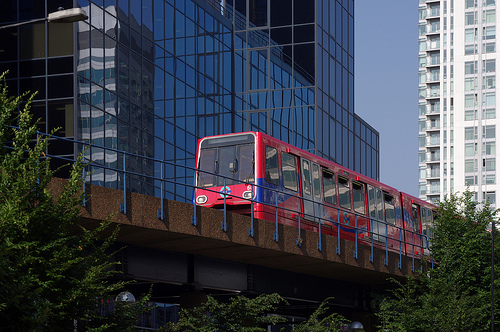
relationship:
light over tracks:
[45, 5, 89, 27] [1, 166, 500, 290]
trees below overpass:
[375, 189, 499, 332] [1, 118, 499, 315]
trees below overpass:
[163, 287, 350, 332] [1, 118, 499, 315]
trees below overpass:
[1, 65, 165, 331] [1, 118, 499, 315]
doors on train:
[296, 153, 328, 228] [186, 128, 500, 273]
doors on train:
[365, 178, 391, 244] [186, 128, 500, 273]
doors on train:
[418, 201, 441, 260] [186, 128, 500, 273]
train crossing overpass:
[186, 128, 500, 273] [1, 118, 499, 315]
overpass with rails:
[1, 118, 499, 315] [0, 119, 499, 283]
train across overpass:
[186, 128, 500, 273] [1, 118, 499, 315]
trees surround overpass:
[375, 189, 499, 332] [1, 118, 499, 315]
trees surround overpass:
[163, 287, 350, 332] [1, 118, 499, 315]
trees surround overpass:
[1, 65, 165, 331] [1, 118, 499, 315]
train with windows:
[186, 128, 500, 273] [262, 143, 284, 187]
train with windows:
[186, 128, 500, 273] [279, 147, 299, 194]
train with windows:
[186, 128, 500, 273] [318, 163, 340, 208]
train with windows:
[186, 128, 500, 273] [334, 170, 354, 212]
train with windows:
[186, 128, 500, 273] [350, 177, 364, 216]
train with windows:
[186, 128, 500, 273] [380, 191, 399, 229]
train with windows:
[186, 128, 500, 273] [409, 202, 422, 234]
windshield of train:
[196, 139, 255, 193] [186, 128, 500, 273]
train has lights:
[186, 128, 500, 273] [241, 190, 257, 200]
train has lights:
[186, 128, 500, 273] [196, 193, 208, 204]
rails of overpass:
[0, 119, 499, 283] [1, 118, 499, 315]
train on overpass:
[186, 128, 500, 273] [1, 118, 499, 315]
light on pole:
[45, 5, 89, 27] [44, 16, 52, 175]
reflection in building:
[74, 3, 163, 198] [1, 1, 390, 331]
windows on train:
[262, 143, 284, 187] [186, 128, 500, 273]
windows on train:
[279, 147, 299, 194] [186, 128, 500, 273]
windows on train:
[318, 163, 340, 208] [186, 128, 500, 273]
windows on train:
[334, 170, 354, 212] [186, 128, 500, 273]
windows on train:
[350, 177, 364, 216] [186, 128, 500, 273]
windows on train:
[380, 191, 399, 229] [186, 128, 500, 273]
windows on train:
[409, 202, 422, 234] [186, 128, 500, 273]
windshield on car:
[196, 139, 255, 193] [189, 129, 408, 259]